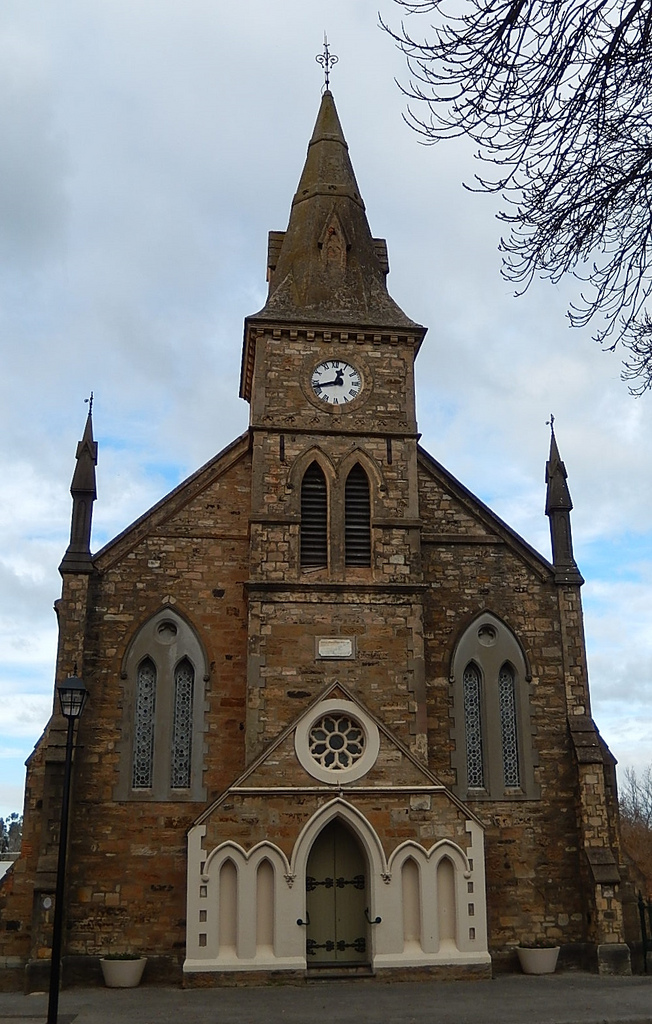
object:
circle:
[294, 699, 381, 786]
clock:
[299, 343, 374, 412]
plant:
[104, 952, 141, 961]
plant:
[518, 936, 557, 950]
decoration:
[307, 707, 366, 768]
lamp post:
[48, 659, 92, 1024]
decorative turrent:
[545, 413, 575, 567]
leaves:
[616, 762, 652, 830]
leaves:
[379, 0, 652, 400]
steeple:
[241, 35, 428, 402]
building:
[0, 28, 652, 992]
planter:
[514, 931, 560, 975]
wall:
[418, 455, 583, 969]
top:
[70, 391, 99, 500]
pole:
[58, 391, 102, 575]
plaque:
[315, 635, 356, 659]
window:
[449, 608, 542, 802]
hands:
[313, 369, 345, 389]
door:
[305, 813, 372, 967]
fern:
[99, 952, 148, 988]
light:
[56, 677, 90, 720]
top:
[316, 28, 340, 86]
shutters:
[299, 458, 330, 573]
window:
[114, 607, 209, 804]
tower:
[236, 28, 428, 764]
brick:
[278, 542, 289, 551]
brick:
[167, 551, 188, 560]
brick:
[183, 570, 203, 579]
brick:
[148, 559, 161, 568]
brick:
[83, 753, 99, 762]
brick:
[102, 826, 112, 834]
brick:
[105, 893, 119, 906]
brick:
[442, 581, 458, 587]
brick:
[465, 589, 479, 594]